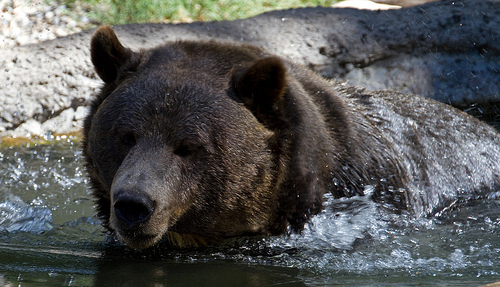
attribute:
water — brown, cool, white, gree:
[316, 215, 358, 246]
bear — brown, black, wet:
[84, 20, 488, 252]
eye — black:
[169, 140, 194, 155]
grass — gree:
[105, 2, 140, 16]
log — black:
[285, 8, 497, 58]